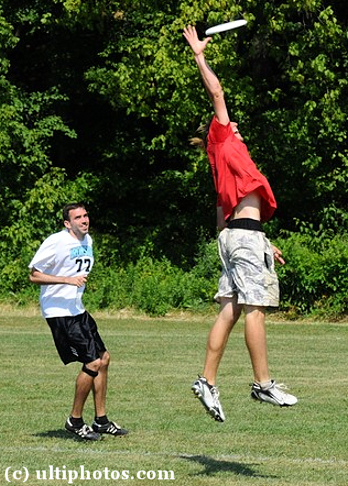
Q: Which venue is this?
A: This is a field.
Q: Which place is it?
A: It is a field.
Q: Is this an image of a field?
A: Yes, it is showing a field.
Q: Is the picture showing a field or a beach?
A: It is showing a field.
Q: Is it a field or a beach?
A: It is a field.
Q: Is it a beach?
A: No, it is a field.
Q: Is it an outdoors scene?
A: Yes, it is outdoors.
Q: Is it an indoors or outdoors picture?
A: It is outdoors.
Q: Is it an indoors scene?
A: No, it is outdoors.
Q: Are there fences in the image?
A: No, there are no fences.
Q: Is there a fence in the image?
A: No, there are no fences.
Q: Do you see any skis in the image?
A: No, there are no skis.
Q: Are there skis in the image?
A: No, there are no skis.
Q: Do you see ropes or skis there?
A: No, there are no skis or ropes.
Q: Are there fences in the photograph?
A: No, there are no fences.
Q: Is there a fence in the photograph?
A: No, there are no fences.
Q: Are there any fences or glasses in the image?
A: No, there are no fences or glasses.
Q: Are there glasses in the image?
A: No, there are no glasses.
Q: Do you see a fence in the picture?
A: No, there are no fences.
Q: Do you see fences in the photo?
A: No, there are no fences.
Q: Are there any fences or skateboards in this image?
A: No, there are no fences or skateboards.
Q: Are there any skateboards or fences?
A: No, there are no fences or skateboards.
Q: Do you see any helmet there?
A: No, there are no helmets.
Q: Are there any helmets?
A: No, there are no helmets.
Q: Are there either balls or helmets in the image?
A: No, there are no helmets or balls.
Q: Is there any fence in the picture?
A: No, there are no fences.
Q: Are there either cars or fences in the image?
A: No, there are no fences or cars.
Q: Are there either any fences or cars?
A: No, there are no fences or cars.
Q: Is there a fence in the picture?
A: No, there are no fences.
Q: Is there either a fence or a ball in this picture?
A: No, there are no fences or balls.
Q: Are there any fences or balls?
A: No, there are no fences or balls.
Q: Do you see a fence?
A: No, there are no fences.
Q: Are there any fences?
A: No, there are no fences.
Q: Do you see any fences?
A: No, there are no fences.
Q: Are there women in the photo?
A: No, there are no women.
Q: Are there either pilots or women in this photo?
A: No, there are no women or pilots.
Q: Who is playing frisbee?
A: The man is playing frisbee.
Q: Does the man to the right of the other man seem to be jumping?
A: Yes, the man is jumping.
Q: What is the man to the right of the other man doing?
A: The man is jumping.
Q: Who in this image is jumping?
A: The man is jumping.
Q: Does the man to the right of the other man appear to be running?
A: No, the man is jumping.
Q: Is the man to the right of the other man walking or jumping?
A: The man is jumping.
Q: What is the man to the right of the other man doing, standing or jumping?
A: The man is jumping.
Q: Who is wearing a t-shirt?
A: The man is wearing a t-shirt.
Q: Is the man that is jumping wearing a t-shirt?
A: Yes, the man is wearing a t-shirt.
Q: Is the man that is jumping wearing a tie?
A: No, the man is wearing a t-shirt.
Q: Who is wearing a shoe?
A: The man is wearing a shoe.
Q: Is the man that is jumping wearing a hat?
A: No, the man is wearing a shoe.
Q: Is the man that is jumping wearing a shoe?
A: Yes, the man is wearing a shoe.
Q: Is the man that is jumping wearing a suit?
A: No, the man is wearing a shoe.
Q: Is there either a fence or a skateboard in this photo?
A: No, there are no fences or skateboards.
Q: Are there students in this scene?
A: No, there are no students.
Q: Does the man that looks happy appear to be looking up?
A: Yes, the man is looking up.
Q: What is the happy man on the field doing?
A: The man is looking up.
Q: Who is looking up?
A: The man is looking up.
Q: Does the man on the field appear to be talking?
A: No, the man is looking up.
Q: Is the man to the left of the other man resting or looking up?
A: The man is looking up.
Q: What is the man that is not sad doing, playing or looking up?
A: The man is looking up.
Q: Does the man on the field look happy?
A: Yes, the man is happy.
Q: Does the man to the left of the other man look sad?
A: No, the man is happy.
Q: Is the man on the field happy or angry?
A: The man is happy.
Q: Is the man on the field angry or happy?
A: The man is happy.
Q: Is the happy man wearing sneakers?
A: Yes, the man is wearing sneakers.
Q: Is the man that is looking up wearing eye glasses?
A: No, the man is wearing sneakers.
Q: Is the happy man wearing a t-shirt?
A: Yes, the man is wearing a t-shirt.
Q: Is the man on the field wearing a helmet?
A: No, the man is wearing a t-shirt.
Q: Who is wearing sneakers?
A: The man is wearing sneakers.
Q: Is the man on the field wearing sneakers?
A: Yes, the man is wearing sneakers.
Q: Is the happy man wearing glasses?
A: No, the man is wearing sneakers.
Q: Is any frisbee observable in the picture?
A: Yes, there is a frisbee.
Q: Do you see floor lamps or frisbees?
A: Yes, there is a frisbee.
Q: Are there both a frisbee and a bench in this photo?
A: No, there is a frisbee but no benches.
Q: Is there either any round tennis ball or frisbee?
A: Yes, there is a round frisbee.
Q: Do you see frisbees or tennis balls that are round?
A: Yes, the frisbee is round.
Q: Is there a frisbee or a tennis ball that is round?
A: Yes, the frisbee is round.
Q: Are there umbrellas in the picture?
A: No, there are no umbrellas.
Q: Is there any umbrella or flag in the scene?
A: No, there are no umbrellas or flags.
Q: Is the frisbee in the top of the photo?
A: Yes, the frisbee is in the top of the image.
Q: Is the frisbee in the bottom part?
A: No, the frisbee is in the top of the image.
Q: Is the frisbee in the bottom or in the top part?
A: The frisbee is in the top of the image.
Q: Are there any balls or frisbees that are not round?
A: No, there is a frisbee but it is round.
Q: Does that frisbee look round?
A: Yes, the frisbee is round.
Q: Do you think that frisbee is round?
A: Yes, the frisbee is round.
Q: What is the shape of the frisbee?
A: The frisbee is round.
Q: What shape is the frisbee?
A: The frisbee is round.